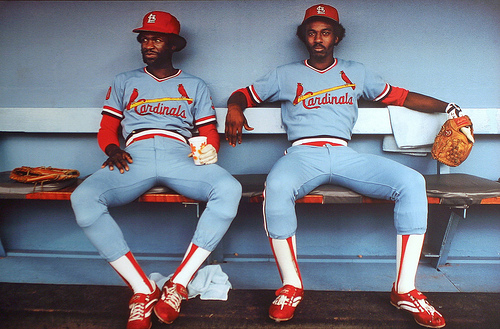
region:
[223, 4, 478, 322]
a St. Louis Cardinals baseball player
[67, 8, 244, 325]
a St. Louis Cardinals baseball player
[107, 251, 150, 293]
a red and white sock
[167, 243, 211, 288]
a red and white sock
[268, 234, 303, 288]
a red and white sock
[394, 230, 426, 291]
a red and white sock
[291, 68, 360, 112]
St. Louis Cardinals club logo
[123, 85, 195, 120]
St. Louis Cardinals club logo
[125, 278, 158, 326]
a red and white shoe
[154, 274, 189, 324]
a red and white shoe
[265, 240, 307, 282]
it is the white and red sock of a player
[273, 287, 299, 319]
the ball player wearing red shoes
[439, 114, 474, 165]
the glove is light brown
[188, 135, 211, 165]
player holding a white cup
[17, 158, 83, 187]
baseball glove laying on bench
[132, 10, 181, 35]
the baseball player is wearing a red hat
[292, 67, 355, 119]
cardinals written on the jersey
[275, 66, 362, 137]
man is wearing blue baseball jersey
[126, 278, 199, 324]
red baseball shoes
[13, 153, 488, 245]
a bench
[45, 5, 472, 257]
two baseball players sitting down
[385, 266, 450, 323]
left foot of the player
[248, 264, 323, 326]
right foot of the player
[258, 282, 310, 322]
red and white shoe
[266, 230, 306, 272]
red and white sock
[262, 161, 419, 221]
blue pants on man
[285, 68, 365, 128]
team logo on jersey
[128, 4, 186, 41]
red and white hat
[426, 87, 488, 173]
glove in person's hand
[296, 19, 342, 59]
face of the player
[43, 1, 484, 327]
men sitting on a bench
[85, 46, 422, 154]
men's shirts are blue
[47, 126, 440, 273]
men's pants are blue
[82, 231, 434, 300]
men's socks are red and white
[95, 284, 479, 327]
men's shoes are red and white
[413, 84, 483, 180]
man is holding a baseball mit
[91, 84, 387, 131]
red letters on men's shirts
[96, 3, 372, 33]
men wearing red hats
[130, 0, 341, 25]
white letter on men's hats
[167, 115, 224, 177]
man holding a cup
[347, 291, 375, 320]
part of a floor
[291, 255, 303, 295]
part of a line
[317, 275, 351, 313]
part of a floor